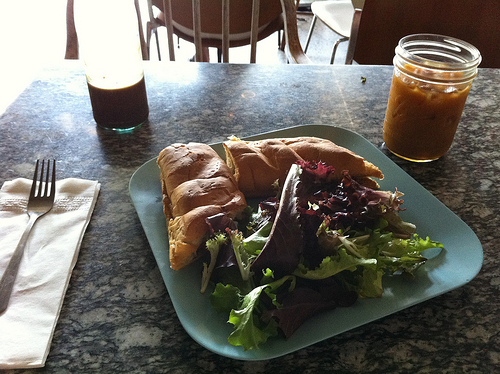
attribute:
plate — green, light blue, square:
[101, 124, 498, 361]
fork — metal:
[12, 139, 75, 319]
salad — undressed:
[201, 172, 430, 346]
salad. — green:
[198, 195, 445, 354]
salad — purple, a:
[243, 200, 394, 272]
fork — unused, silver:
[0, 157, 59, 315]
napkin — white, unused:
[6, 152, 89, 372]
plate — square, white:
[115, 110, 465, 370]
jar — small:
[380, 34, 481, 166]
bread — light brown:
[159, 122, 389, 267]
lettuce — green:
[249, 149, 318, 274]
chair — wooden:
[55, 5, 325, 61]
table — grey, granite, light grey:
[1, 53, 499, 371]